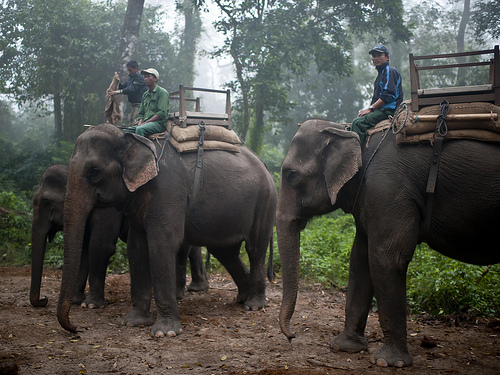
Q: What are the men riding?
A: Elephants.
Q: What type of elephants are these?
A: Asian elephants.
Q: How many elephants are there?
A: Three.